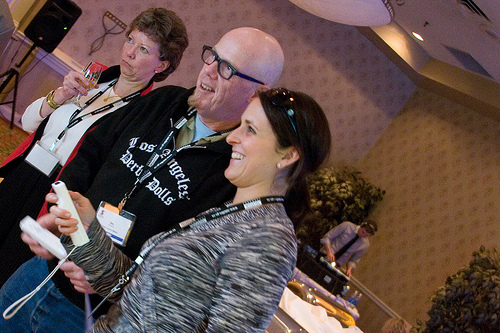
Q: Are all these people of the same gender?
A: No, they are both male and female.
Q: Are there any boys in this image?
A: No, there are no boys.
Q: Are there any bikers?
A: No, there are no bikers.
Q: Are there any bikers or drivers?
A: No, there are no bikers or drivers.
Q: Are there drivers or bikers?
A: No, there are no bikers or drivers.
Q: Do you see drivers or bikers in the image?
A: No, there are no bikers or drivers.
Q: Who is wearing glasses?
A: The man is wearing glasses.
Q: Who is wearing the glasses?
A: The man is wearing glasses.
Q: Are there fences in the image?
A: No, there are no fences.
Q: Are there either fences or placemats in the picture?
A: No, there are no fences or placemats.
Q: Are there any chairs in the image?
A: No, there are no chairs.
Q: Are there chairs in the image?
A: No, there are no chairs.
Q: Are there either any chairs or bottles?
A: No, there are no chairs or bottles.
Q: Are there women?
A: Yes, there is a woman.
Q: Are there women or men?
A: Yes, there is a woman.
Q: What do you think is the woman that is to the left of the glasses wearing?
A: The woman is wearing a shirt.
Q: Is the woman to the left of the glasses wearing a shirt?
A: Yes, the woman is wearing a shirt.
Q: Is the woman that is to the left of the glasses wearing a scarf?
A: No, the woman is wearing a shirt.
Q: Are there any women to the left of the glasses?
A: Yes, there is a woman to the left of the glasses.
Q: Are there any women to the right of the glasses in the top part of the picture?
A: No, the woman is to the left of the glasses.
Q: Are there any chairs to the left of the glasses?
A: No, there is a woman to the left of the glasses.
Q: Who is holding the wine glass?
A: The woman is holding the wine glass.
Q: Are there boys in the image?
A: No, there are no boys.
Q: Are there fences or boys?
A: No, there are no boys or fences.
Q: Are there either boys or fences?
A: No, there are no boys or fences.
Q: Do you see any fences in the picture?
A: No, there are no fences.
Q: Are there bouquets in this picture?
A: No, there are no bouquets.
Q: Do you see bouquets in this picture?
A: No, there are no bouquets.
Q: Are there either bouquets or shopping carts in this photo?
A: No, there are no bouquets or shopping carts.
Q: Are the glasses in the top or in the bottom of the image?
A: The glasses are in the top of the image.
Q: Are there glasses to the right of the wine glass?
A: Yes, there are glasses to the right of the wine glass.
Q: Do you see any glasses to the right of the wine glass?
A: Yes, there are glasses to the right of the wine glass.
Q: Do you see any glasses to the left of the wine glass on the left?
A: No, the glasses are to the right of the wine glass.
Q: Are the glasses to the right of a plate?
A: No, the glasses are to the right of the wine glass.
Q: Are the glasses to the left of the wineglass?
A: No, the glasses are to the right of the wineglass.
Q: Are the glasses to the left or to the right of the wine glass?
A: The glasses are to the right of the wine glass.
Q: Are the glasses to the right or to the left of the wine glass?
A: The glasses are to the right of the wine glass.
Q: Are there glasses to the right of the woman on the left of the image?
A: Yes, there are glasses to the right of the woman.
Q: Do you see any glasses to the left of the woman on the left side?
A: No, the glasses are to the right of the woman.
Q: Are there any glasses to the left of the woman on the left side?
A: No, the glasses are to the right of the woman.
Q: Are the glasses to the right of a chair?
A: No, the glasses are to the right of a woman.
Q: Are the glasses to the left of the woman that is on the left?
A: No, the glasses are to the right of the woman.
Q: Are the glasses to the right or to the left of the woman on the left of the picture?
A: The glasses are to the right of the woman.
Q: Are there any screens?
A: No, there are no screens.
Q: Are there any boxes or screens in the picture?
A: No, there are no screens or boxes.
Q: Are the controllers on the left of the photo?
A: Yes, the controllers are on the left of the image.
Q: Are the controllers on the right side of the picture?
A: No, the controllers are on the left of the image.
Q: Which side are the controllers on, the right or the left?
A: The controllers are on the left of the image.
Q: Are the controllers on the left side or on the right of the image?
A: The controllers are on the left of the image.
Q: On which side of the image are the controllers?
A: The controllers are on the left of the image.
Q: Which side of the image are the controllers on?
A: The controllers are on the left of the image.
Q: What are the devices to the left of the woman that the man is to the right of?
A: The devices are controllers.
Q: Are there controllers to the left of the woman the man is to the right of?
A: Yes, there are controllers to the left of the woman.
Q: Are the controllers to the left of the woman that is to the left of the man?
A: Yes, the controllers are to the left of the woman.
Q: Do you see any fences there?
A: No, there are no fences.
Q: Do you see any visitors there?
A: No, there are no visitors.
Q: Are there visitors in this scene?
A: No, there are no visitors.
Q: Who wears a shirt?
A: The man wears a shirt.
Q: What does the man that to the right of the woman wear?
A: The man wears a shirt.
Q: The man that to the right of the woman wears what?
A: The man wears a shirt.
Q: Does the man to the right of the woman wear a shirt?
A: Yes, the man wears a shirt.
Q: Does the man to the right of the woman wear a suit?
A: No, the man wears a shirt.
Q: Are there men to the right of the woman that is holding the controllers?
A: Yes, there is a man to the right of the woman.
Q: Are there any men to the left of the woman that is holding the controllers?
A: No, the man is to the right of the woman.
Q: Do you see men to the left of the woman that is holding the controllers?
A: No, the man is to the right of the woman.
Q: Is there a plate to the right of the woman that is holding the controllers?
A: No, there is a man to the right of the woman.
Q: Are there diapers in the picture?
A: No, there are no diapers.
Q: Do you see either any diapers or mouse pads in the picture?
A: No, there are no diapers or mouse pads.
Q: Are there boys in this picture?
A: No, there are no boys.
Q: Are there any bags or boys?
A: No, there are no boys or bags.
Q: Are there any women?
A: Yes, there is a woman.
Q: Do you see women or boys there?
A: Yes, there is a woman.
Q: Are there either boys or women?
A: Yes, there is a woman.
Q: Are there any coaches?
A: No, there are no coaches.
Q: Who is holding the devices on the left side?
A: The woman is holding the controllers.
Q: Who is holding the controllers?
A: The woman is holding the controllers.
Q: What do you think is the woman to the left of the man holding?
A: The woman is holding the controllers.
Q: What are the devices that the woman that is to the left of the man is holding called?
A: The devices are controllers.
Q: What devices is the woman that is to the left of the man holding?
A: The woman is holding the controllers.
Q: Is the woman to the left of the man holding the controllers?
A: Yes, the woman is holding the controllers.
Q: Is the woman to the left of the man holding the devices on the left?
A: Yes, the woman is holding the controllers.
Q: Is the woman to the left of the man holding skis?
A: No, the woman is holding the controllers.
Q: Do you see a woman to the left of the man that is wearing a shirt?
A: Yes, there is a woman to the left of the man.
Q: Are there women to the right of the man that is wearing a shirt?
A: No, the woman is to the left of the man.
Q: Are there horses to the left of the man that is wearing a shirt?
A: No, there is a woman to the left of the man.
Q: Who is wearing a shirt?
A: The woman is wearing a shirt.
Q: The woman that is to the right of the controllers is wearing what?
A: The woman is wearing a shirt.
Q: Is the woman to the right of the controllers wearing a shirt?
A: Yes, the woman is wearing a shirt.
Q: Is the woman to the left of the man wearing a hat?
A: No, the woman is wearing a shirt.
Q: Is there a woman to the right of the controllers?
A: Yes, there is a woman to the right of the controllers.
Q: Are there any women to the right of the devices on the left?
A: Yes, there is a woman to the right of the controllers.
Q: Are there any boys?
A: No, there are no boys.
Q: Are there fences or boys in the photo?
A: No, there are no boys or fences.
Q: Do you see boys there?
A: No, there are no boys.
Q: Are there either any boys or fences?
A: No, there are no boys or fences.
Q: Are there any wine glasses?
A: Yes, there is a wine glass.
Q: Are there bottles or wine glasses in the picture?
A: Yes, there is a wine glass.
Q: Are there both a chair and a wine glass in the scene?
A: No, there is a wine glass but no chairs.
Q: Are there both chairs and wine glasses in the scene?
A: No, there is a wine glass but no chairs.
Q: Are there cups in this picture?
A: No, there are no cups.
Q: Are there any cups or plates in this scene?
A: No, there are no cups or plates.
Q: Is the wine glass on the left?
A: Yes, the wine glass is on the left of the image.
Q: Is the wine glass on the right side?
A: No, the wine glass is on the left of the image.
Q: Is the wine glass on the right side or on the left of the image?
A: The wine glass is on the left of the image.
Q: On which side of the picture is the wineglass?
A: The wineglass is on the left of the image.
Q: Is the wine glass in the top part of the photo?
A: Yes, the wine glass is in the top of the image.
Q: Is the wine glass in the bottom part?
A: No, the wine glass is in the top of the image.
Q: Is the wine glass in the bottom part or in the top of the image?
A: The wine glass is in the top of the image.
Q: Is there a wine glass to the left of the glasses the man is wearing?
A: Yes, there is a wine glass to the left of the glasses.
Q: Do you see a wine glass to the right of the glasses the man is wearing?
A: No, the wine glass is to the left of the glasses.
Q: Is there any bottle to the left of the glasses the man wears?
A: No, there is a wine glass to the left of the glasses.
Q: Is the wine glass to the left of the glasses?
A: Yes, the wine glass is to the left of the glasses.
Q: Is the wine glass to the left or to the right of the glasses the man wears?
A: The wine glass is to the left of the glasses.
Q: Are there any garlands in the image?
A: No, there are no garlands.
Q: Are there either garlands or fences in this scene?
A: No, there are no garlands or fences.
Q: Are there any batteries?
A: No, there are no batteries.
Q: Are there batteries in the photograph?
A: No, there are no batteries.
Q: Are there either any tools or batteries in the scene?
A: No, there are no batteries or tools.